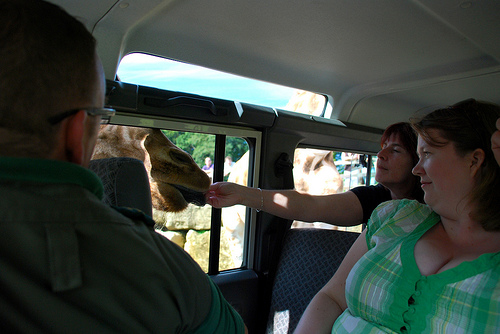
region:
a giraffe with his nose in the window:
[106, 110, 218, 220]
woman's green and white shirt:
[363, 194, 448, 316]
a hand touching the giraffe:
[178, 142, 253, 226]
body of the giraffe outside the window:
[233, 79, 350, 197]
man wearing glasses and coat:
[22, 42, 202, 306]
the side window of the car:
[123, 98, 290, 283]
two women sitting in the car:
[343, 113, 495, 286]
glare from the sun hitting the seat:
[259, 296, 290, 332]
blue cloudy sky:
[176, 65, 239, 99]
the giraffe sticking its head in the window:
[97, 122, 209, 212]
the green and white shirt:
[336, 196, 493, 332]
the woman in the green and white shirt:
[296, 96, 498, 331]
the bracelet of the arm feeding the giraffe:
[255, 185, 265, 212]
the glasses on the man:
[58, 107, 114, 127]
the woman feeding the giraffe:
[207, 122, 414, 224]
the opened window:
[98, 111, 255, 275]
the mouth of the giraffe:
[156, 175, 211, 207]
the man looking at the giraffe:
[0, 0, 215, 332]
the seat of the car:
[276, 229, 334, 311]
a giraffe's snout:
[93, 120, 210, 220]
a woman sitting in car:
[308, 107, 498, 332]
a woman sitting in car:
[204, 116, 421, 228]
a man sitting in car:
[5, 2, 252, 327]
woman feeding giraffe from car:
[99, 120, 412, 212]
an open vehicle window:
[86, 116, 220, 282]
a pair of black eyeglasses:
[60, 101, 113, 133]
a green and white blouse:
[334, 192, 488, 331]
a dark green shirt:
[4, 165, 246, 329]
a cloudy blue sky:
[118, 50, 295, 105]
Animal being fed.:
[94, 117, 211, 221]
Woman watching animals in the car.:
[283, 98, 497, 332]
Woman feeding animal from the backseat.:
[206, 118, 438, 228]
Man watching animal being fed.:
[3, 6, 255, 333]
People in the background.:
[197, 148, 240, 197]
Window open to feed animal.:
[97, 123, 254, 279]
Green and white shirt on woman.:
[329, 194, 499, 332]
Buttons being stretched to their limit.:
[398, 275, 438, 332]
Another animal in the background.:
[211, 84, 353, 266]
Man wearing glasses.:
[79, 91, 120, 131]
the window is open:
[98, 74, 304, 324]